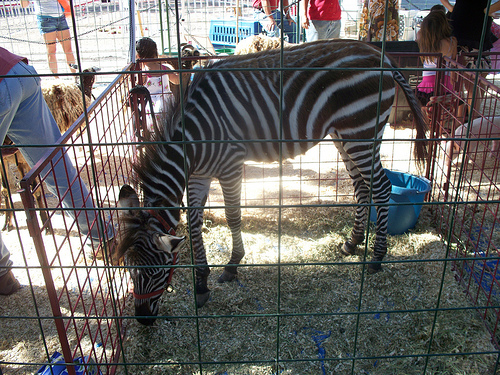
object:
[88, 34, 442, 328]
zebra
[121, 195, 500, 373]
grain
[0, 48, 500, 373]
cage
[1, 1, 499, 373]
wiring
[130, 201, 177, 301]
halter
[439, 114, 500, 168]
pig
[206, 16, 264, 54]
pet carrier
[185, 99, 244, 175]
stripe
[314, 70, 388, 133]
stripe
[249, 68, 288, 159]
stripe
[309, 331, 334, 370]
tarp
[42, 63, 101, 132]
goat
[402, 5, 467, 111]
girl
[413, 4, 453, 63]
hair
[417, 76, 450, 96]
skirt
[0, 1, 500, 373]
petting zoo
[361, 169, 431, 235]
bucket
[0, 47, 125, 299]
person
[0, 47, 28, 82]
shirt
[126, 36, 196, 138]
girl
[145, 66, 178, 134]
dress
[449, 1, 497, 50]
top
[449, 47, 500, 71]
shorts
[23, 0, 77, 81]
woman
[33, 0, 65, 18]
shirt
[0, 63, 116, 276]
jeans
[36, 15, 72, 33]
shorts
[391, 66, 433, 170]
tail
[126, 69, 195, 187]
mane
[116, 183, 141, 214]
ear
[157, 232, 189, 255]
ear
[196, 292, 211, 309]
hoof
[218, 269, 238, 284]
hoof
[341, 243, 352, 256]
hoof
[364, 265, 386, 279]
hoof